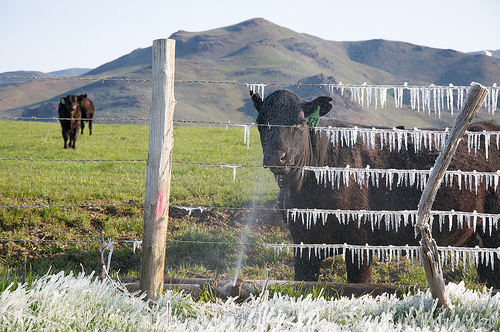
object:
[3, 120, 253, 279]
field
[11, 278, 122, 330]
grass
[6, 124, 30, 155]
grass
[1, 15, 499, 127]
mountain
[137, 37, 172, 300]
pole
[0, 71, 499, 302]
fence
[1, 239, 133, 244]
wire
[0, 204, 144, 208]
wire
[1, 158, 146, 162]
wire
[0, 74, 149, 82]
wire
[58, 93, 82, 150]
cow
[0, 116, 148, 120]
wire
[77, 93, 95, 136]
cow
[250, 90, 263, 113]
ear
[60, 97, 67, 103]
ear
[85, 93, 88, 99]
ear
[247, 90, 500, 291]
cow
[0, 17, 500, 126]
hills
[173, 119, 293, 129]
wire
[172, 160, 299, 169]
wire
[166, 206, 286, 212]
wire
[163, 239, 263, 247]
wire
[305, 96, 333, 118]
ear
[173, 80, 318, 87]
wire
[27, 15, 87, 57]
sky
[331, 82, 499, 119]
icicles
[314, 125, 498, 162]
icicles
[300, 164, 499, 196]
icicles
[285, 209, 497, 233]
icicles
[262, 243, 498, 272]
icicles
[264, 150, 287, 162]
nose